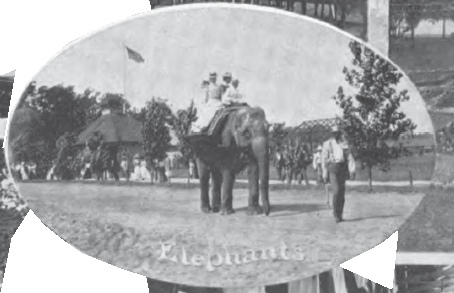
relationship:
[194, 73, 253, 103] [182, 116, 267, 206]
people on elephant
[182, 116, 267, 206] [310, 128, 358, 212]
elephant behind man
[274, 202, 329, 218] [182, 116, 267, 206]
shadow of elephant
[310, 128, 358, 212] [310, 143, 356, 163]
man in white shirt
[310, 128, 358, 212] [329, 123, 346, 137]
man in hat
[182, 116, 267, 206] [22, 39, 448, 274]
elephant in photo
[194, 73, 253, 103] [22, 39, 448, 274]
people in photo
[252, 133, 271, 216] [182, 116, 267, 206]
trunk of elephant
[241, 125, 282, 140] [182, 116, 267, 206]
eyes of elephant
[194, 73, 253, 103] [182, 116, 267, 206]
people sitting on elephant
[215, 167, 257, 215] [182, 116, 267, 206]
legs of elephant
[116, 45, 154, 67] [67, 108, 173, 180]
flag on building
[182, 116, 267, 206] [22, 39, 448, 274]
elephant on photo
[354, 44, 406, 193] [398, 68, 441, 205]
tree on right of photo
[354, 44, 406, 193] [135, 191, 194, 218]
tree by walkway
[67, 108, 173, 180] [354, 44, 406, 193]
building behind tree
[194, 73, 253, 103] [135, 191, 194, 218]
people on walkway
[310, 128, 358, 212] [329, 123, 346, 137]
man wearing hat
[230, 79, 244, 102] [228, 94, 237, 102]
woman in white dress